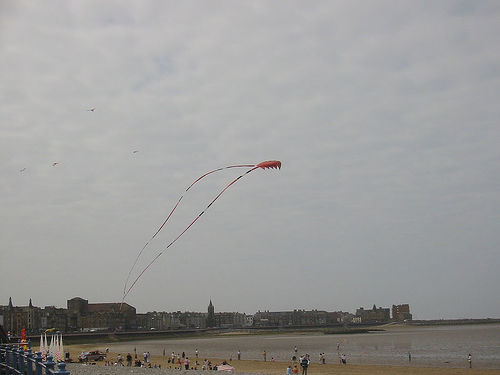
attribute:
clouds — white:
[301, 24, 434, 283]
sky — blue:
[8, 62, 430, 273]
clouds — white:
[126, 58, 435, 267]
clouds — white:
[215, 218, 411, 296]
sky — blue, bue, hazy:
[0, 9, 482, 291]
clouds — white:
[301, 50, 458, 259]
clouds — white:
[1, 45, 399, 305]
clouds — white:
[38, 13, 448, 139]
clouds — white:
[295, 50, 464, 290]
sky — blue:
[3, 17, 445, 293]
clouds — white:
[0, 22, 471, 282]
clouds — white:
[284, 11, 454, 273]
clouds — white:
[284, 39, 466, 290]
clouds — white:
[40, 70, 450, 270]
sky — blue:
[0, 30, 463, 286]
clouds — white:
[79, 66, 366, 233]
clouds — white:
[6, 5, 466, 290]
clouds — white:
[7, 1, 414, 282]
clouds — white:
[49, 21, 446, 121]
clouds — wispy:
[103, 83, 386, 137]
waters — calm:
[355, 333, 475, 358]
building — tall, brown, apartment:
[61, 294, 140, 333]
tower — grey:
[199, 297, 219, 328]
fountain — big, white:
[30, 325, 70, 362]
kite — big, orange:
[190, 156, 291, 181]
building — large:
[49, 293, 142, 337]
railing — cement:
[3, 338, 55, 368]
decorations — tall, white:
[31, 329, 71, 370]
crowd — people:
[121, 342, 224, 373]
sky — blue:
[8, 17, 492, 303]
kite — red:
[233, 158, 287, 173]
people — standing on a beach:
[101, 353, 331, 370]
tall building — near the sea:
[204, 297, 218, 329]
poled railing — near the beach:
[0, 344, 68, 373]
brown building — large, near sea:
[53, 294, 138, 330]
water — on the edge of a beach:
[135, 347, 344, 361]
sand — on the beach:
[81, 346, 215, 373]